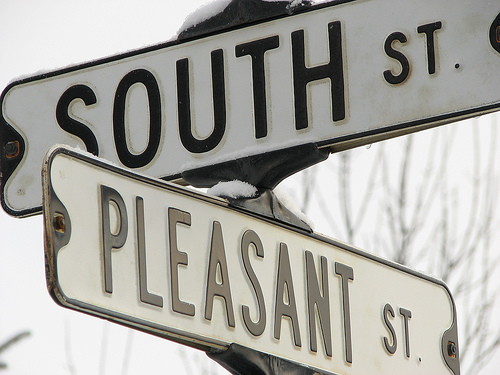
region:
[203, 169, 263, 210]
snow on the sign pole.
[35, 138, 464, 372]
Sign on the pole.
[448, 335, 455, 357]
screw in the sign.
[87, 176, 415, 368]
black letters on the sign.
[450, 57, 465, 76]
black dot on the sign.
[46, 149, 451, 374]
White coloring on the sign.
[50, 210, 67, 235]
Rust on the bolt.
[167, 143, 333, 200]
Black bracket holding the sign.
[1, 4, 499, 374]
street signs at an intersection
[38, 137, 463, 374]
one sign is for Pleasant St.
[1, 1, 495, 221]
one sign is for South St.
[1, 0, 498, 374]
the street signs are perpendicular to each other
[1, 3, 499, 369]
the signs are outlined in black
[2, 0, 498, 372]
the signs have black lettering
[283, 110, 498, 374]
a leafless tree in the background behind the signs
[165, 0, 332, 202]
little piles of snow on the street sign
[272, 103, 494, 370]
the absence of leaves indicates wintertime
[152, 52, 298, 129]
Text on the sign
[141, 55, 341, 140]
Metal plate on the sign post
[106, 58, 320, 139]
Black text in the photo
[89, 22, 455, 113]
South St. written on the plate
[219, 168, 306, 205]
Metal stand in the photo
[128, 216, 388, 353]
Gray text on the signage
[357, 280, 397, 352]
White color on the plate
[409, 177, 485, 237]
Trees growing in the background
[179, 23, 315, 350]
Road signs giving directions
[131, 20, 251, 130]
Black and white street sign on pole.Black and white street sign on pole.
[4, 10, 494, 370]
Two standard sign board plates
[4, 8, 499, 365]
Different directions show by the sign board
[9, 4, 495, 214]
A sign board indicating South st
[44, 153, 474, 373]
A board indicating Pleasant st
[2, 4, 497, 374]
A pole holding the sign board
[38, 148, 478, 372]
A small screw is fixed at the end of the sign board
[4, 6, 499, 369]
During winter season ice is spread on the board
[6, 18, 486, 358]
A big wall is present behind the sign board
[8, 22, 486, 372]
Name of the street written in big letters